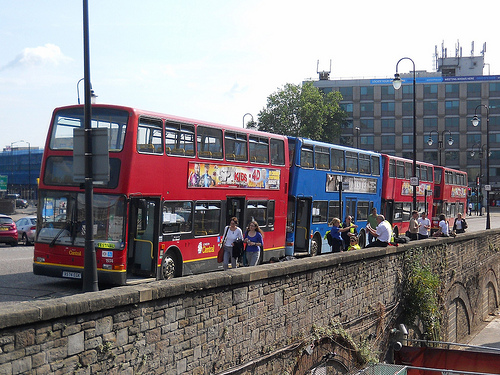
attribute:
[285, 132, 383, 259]
section — blue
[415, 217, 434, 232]
shirt — white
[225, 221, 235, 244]
sweater — white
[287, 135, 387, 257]
bus — blue 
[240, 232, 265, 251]
shirt — purple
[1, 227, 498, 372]
stone bridge — historical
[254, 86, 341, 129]
tree — tall, green, behind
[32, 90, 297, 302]
bus — red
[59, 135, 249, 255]
bus — red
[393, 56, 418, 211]
lamp — tall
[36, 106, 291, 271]
bus — red 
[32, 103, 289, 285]
bus — red